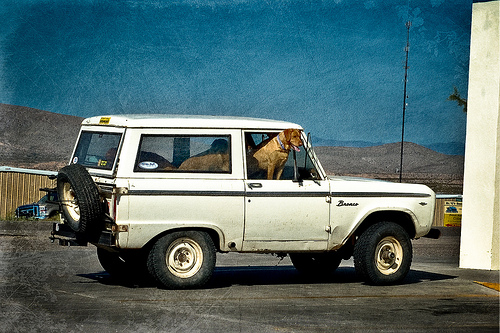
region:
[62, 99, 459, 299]
white SUV with dog at passenger window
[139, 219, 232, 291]
dirty black back tire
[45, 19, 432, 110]
bright blue sky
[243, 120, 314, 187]
brown dog at passenger window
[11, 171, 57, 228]
blue and white truck parked beside fence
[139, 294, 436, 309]
yellow line on black pavement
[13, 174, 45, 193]
brown wood fence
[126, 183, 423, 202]
black like on side of white vehicle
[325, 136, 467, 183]
mountains in background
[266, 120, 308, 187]
dog with blue collar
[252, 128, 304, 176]
tan dog hanging out window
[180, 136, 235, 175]
tan dog sitting in car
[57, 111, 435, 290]
black and white jeep vehicle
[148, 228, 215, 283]
black rubber tire with white hubcaps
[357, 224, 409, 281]
black rubber tires with hubcaps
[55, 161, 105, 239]
black rubber tires with white hubcap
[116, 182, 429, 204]
black stripe of jeep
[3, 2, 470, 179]
bright blue sky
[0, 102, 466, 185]
tan mountain range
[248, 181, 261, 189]
silver door handle of jeep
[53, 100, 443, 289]
the jeep is white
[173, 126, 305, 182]
the dogs are brown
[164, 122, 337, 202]
the dogs are in the jeep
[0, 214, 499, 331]
the pavement is black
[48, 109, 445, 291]
the jeep is parked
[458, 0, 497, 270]
the building is white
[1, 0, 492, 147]
the sky is blue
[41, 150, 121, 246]
the tire is a spare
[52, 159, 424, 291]
the tires are black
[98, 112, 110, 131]
the jeep has a yellow sticker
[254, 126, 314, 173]
dog in truck window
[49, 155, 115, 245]
tire on back of truck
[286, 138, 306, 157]
open mouth on dog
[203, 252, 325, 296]
shadow under truck body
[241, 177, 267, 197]
handle on truck door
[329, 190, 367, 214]
name of vehicle make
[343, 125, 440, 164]
hills on the horizon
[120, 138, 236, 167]
dogs inside of truck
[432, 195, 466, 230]
sign on side of building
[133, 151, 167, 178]
sticker on car window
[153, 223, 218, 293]
the tire of a vehicle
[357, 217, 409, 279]
the tire of a vehicle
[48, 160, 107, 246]
the tire of a vehicle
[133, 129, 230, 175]
the window of a vehicle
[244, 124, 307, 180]
the window of a vehicle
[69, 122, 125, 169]
the window of a vehicle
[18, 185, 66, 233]
a vehicle parked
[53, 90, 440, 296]
a white vehicle parked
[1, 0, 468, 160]
a clear blue sky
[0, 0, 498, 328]
it is a daytime scene